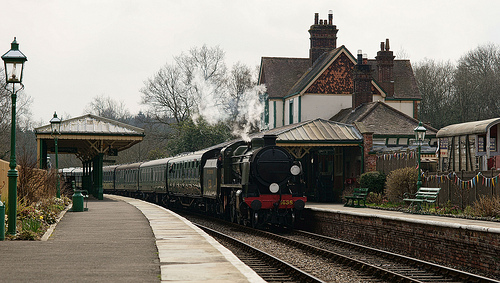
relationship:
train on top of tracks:
[46, 143, 304, 232] [199, 207, 491, 282]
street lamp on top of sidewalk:
[3, 35, 25, 239] [4, 192, 199, 282]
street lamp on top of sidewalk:
[47, 108, 66, 211] [4, 192, 199, 282]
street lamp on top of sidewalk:
[407, 119, 432, 209] [333, 202, 498, 234]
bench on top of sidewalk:
[70, 179, 87, 208] [4, 192, 199, 282]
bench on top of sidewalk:
[402, 187, 450, 215] [333, 202, 498, 234]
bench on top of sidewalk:
[342, 186, 372, 209] [333, 202, 498, 234]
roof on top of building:
[252, 50, 422, 91] [255, 16, 424, 188]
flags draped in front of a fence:
[421, 175, 499, 191] [377, 156, 499, 214]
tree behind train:
[151, 49, 242, 150] [46, 143, 304, 232]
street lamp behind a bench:
[47, 108, 66, 211] [70, 179, 87, 208]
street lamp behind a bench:
[407, 119, 432, 209] [402, 187, 450, 215]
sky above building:
[5, 1, 494, 62] [255, 16, 424, 188]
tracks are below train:
[199, 207, 491, 282] [46, 143, 304, 232]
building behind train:
[255, 16, 424, 188] [46, 143, 304, 232]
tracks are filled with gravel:
[199, 207, 491, 282] [308, 255, 327, 281]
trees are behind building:
[422, 54, 493, 124] [255, 16, 424, 188]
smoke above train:
[186, 69, 267, 136] [46, 143, 304, 232]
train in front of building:
[46, 143, 304, 232] [255, 16, 424, 188]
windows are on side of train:
[110, 163, 203, 183] [46, 143, 304, 232]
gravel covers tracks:
[308, 255, 327, 281] [199, 207, 491, 282]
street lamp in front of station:
[407, 119, 432, 209] [255, 16, 424, 188]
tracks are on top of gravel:
[199, 207, 491, 282] [308, 255, 327, 281]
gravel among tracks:
[308, 255, 327, 281] [199, 207, 491, 282]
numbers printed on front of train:
[276, 197, 300, 213] [46, 143, 304, 232]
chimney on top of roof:
[308, 5, 335, 76] [252, 50, 422, 91]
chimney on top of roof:
[375, 37, 399, 103] [252, 50, 422, 91]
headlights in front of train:
[271, 163, 305, 194] [46, 143, 304, 232]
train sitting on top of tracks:
[46, 143, 304, 232] [199, 207, 491, 282]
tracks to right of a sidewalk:
[199, 207, 491, 282] [4, 192, 199, 282]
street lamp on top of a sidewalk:
[3, 35, 25, 239] [4, 192, 199, 282]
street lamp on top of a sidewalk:
[47, 108, 66, 211] [4, 192, 199, 282]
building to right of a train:
[255, 16, 424, 188] [46, 143, 304, 232]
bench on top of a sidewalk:
[402, 187, 450, 215] [333, 202, 498, 234]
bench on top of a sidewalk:
[342, 186, 372, 209] [333, 202, 498, 234]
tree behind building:
[151, 49, 242, 150] [255, 16, 424, 188]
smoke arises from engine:
[186, 69, 267, 136] [224, 132, 293, 192]